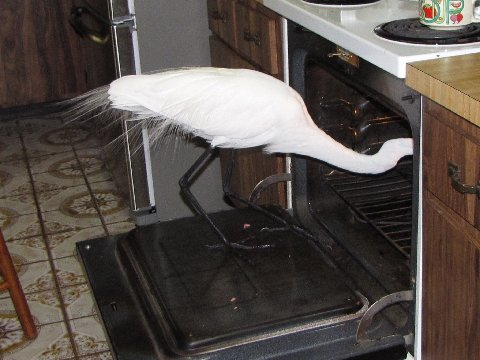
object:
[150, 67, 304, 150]
body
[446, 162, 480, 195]
metal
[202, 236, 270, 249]
feet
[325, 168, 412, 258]
rack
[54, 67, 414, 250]
bird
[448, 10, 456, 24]
vegetables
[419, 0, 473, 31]
cup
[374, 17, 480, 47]
burner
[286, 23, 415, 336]
open oven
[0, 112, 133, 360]
floor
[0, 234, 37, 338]
leg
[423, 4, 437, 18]
logo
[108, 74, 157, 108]
tail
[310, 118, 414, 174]
neck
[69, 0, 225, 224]
refrigerator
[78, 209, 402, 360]
door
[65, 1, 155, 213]
door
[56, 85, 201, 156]
feathers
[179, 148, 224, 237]
leg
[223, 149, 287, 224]
leg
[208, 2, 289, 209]
cabinet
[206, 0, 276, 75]
drawer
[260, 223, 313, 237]
foot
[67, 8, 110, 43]
handle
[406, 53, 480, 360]
cabinet